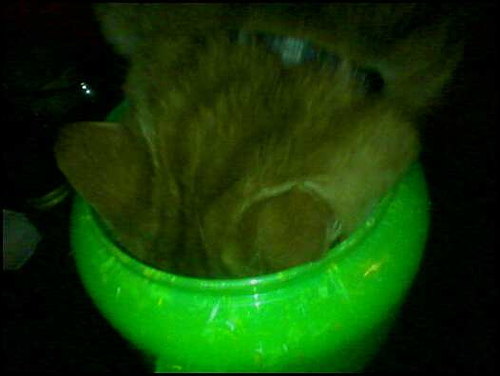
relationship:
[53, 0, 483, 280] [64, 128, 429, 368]
cat in bowl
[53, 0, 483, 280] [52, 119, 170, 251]
cat has ear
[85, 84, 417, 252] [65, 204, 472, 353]
cat's face in bowl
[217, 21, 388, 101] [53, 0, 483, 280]
collar on cat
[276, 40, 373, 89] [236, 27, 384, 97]
clip on collar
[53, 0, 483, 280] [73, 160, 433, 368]
cat eating from jar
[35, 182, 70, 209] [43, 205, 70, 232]
gold lid of jar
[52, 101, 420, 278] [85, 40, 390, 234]
cats head of cat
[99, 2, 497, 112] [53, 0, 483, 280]
body of cat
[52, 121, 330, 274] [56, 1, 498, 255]
cat's ears of cat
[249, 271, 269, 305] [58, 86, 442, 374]
reflection on bowl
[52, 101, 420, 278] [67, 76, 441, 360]
cats head in bowl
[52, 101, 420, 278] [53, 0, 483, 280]
cats head of cat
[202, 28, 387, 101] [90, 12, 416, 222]
collar on cat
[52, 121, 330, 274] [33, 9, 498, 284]
cat's ears of cat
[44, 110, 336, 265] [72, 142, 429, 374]
cat's ears sticking out of bowl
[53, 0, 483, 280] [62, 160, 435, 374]
cat in pot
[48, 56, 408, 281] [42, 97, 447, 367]
cats head in dish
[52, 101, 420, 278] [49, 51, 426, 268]
cats head of cat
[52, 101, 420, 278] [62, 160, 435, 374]
cats head in pot